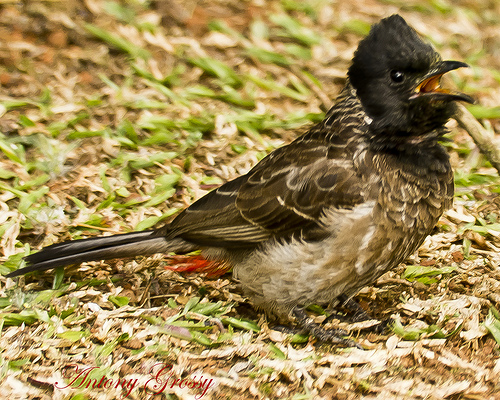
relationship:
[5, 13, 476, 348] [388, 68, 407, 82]
bird has an eye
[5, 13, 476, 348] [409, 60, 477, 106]
bird has a beak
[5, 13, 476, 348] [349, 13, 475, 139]
bird has a head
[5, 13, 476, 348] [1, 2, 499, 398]
bird standing in grass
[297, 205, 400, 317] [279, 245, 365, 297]
stomach has feathers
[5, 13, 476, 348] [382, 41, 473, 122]
bird has a face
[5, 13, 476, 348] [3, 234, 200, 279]
bird has a feather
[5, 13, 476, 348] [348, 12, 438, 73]
bird has hair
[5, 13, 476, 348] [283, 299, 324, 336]
bird has a leg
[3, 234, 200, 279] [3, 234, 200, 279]
feather has feather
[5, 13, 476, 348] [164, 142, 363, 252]
bird has a right wing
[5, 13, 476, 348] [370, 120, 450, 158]
bird has a throat